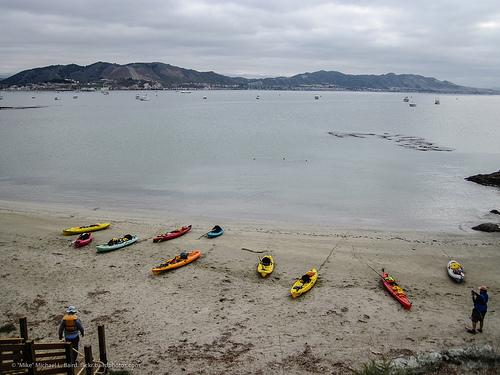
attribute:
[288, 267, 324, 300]
kayak — red, yellow, little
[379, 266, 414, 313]
kayak — red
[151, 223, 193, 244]
kayak — little, red, yellow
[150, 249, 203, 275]
kayak — orange, black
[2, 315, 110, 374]
rail — wooden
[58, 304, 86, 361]
man — standing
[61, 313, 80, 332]
vest — orange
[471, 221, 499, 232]
rock — black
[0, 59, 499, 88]
hills — green, large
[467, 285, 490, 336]
man — standing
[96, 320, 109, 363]
pole — wooden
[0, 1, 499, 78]
clouds — dark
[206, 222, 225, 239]
kayak — teal, blue